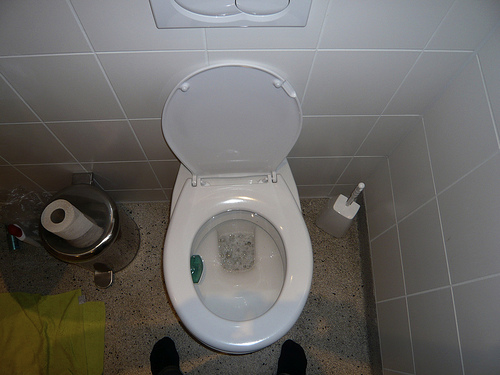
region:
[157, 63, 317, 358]
Open white toilet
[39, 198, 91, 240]
Roll of toilet paper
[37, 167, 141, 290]
Silver foot operated trashcan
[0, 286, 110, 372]
Folded yellow towel on the floor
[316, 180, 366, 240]
White bathroom bowl cleaner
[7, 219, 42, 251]
White plastic bottle with red top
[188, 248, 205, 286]
Green toilet bowl cleaner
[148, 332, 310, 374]
Feet with black socks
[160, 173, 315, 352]
White toilet seat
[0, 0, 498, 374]
Bathroom with white walls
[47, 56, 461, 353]
a white toilet seat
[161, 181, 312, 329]
the toilet bowl is clean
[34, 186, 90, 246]
a roll of toilet paper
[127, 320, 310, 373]
a peson's feet near the toilet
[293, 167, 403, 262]
a toilet brush next to the toilet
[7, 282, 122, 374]
a yellow object in the bathroom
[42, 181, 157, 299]
a stainless steel garbage can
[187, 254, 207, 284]
a green toilet bowl cleaner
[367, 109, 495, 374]
a white wall in the bathroom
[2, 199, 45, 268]
an item near the trash can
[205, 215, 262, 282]
Bubbles in the bowl.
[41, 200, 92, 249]
Toilet paper on the garbage can.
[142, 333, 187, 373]
Right foot in a black sock.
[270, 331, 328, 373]
Left foot in a black sock.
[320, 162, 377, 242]
Scrubber to keep the bowl clean.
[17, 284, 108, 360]
Yellow towel on the floor.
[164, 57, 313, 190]
White lid on the toilet.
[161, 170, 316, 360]
White seat on the bowl.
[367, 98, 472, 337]
White tile walls in the bathroom.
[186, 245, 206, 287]
Something to keep the bowl smelling nice.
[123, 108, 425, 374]
a bathroom toilet that is white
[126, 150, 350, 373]
a white bathroom toilet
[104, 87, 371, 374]
a toilet that is white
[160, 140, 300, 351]
a toilet in the bathroom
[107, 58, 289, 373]
a toilet with lid up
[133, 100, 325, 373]
a toilet with seat down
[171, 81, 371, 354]
a bathroom toilet with lid up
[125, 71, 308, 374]
a bathroom toilet with seat down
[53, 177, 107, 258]
a roll of toilet paper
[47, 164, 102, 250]
a roll of toilet paper on garbage can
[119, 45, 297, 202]
white lid on toilet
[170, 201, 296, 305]
toilet seat is lowered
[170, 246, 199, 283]
green freshener in toilet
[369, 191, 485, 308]
white tile on wall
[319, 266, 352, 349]
floor is light grey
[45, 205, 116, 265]
toilet roll on silver can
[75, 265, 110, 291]
step-latch on silver can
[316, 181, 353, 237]
white brush in holder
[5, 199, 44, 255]
bottle next to can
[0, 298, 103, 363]
yellow towel on floor